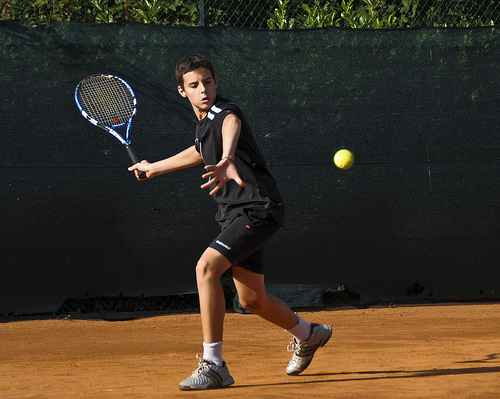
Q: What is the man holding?
A: A tennis racket.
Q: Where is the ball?
A: In the air.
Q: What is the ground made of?
A: Dirt.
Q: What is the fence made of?
A: Chain link.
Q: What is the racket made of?
A: Metal and cord.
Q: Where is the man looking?
A: At the ball.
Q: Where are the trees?
A: Behind the fence.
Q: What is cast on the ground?
A: Shadows.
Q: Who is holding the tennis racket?
A: The man.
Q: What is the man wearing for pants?
A: Black shorts.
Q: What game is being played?
A: Tennis.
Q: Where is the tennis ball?
A: In the air.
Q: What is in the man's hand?
A: Tennis racket.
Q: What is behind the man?
A: A fence.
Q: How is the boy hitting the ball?
A: With a racket.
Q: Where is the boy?
A: On a tennis court.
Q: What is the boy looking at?
A: A tennis ball.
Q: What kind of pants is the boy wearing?
A: Shorts.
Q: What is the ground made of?
A: Dirt.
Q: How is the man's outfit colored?
A: Black.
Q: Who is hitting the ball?
A: The man.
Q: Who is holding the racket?
A: The man.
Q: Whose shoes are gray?
A: The man's.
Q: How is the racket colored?
A: Blue.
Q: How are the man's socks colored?
A: White.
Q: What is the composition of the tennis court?
A: Clay.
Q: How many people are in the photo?
A: One.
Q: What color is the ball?
A: Yellow.